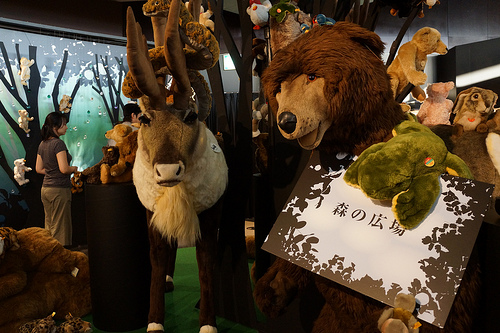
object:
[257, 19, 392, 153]
head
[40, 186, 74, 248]
pants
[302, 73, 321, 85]
eye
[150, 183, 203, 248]
beard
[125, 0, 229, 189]
stuffed head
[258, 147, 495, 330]
sign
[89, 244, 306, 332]
ground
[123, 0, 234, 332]
deer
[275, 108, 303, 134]
nose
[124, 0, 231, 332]
moose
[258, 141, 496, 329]
b&w sign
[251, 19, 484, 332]
bear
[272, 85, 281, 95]
eye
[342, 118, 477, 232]
stuffed toys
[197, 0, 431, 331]
toy tree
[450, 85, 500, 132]
stuffed rabbit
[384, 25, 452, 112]
bear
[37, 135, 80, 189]
shirt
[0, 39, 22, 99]
tree limb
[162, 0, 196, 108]
antler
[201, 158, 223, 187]
white plug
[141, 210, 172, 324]
legs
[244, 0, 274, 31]
bird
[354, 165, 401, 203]
nose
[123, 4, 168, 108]
deer antlers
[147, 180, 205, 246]
hair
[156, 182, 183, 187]
chin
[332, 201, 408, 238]
info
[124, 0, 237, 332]
goat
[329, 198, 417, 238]
lettering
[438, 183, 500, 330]
border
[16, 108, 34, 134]
stuffed anmal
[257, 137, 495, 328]
board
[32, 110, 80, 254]
woman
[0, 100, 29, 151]
branch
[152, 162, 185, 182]
nose